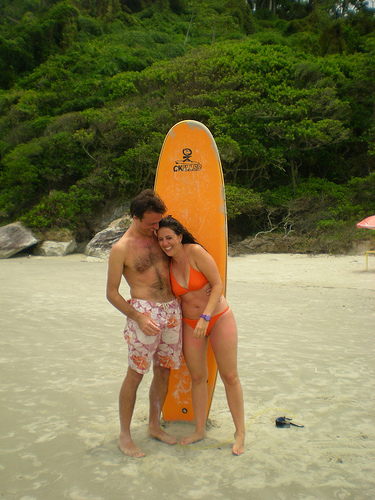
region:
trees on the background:
[30, 124, 124, 225]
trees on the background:
[243, 144, 328, 261]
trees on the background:
[333, 133, 374, 242]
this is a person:
[155, 221, 262, 454]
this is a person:
[86, 189, 180, 469]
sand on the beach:
[30, 351, 96, 436]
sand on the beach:
[65, 377, 118, 443]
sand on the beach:
[260, 441, 310, 480]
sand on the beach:
[253, 304, 324, 365]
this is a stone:
[28, 221, 79, 256]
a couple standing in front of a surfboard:
[65, 116, 246, 472]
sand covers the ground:
[0, 245, 371, 497]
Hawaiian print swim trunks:
[109, 292, 193, 383]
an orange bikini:
[161, 260, 239, 346]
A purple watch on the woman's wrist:
[195, 303, 216, 335]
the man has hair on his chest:
[122, 239, 173, 308]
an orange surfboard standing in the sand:
[137, 103, 237, 431]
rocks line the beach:
[0, 208, 137, 271]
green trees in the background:
[4, 0, 374, 250]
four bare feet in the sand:
[106, 410, 258, 467]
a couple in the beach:
[96, 183, 258, 462]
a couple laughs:
[100, 187, 260, 464]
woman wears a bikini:
[151, 217, 259, 459]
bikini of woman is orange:
[153, 217, 254, 463]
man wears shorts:
[87, 183, 174, 463]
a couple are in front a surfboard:
[101, 113, 257, 466]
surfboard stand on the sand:
[144, 110, 232, 452]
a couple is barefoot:
[94, 180, 264, 472]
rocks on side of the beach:
[6, 191, 133, 262]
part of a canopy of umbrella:
[350, 206, 373, 239]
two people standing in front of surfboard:
[110, 109, 248, 457]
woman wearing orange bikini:
[159, 220, 253, 457]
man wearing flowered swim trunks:
[100, 189, 187, 462]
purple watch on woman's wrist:
[197, 315, 210, 322]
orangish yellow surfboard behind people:
[148, 114, 229, 425]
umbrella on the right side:
[360, 206, 373, 274]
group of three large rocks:
[2, 211, 130, 255]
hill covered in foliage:
[11, 7, 359, 234]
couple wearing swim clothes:
[105, 192, 252, 455]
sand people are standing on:
[7, 256, 363, 496]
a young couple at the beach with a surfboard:
[87, 115, 260, 462]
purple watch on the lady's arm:
[199, 310, 214, 323]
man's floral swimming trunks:
[106, 290, 187, 375]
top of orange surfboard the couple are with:
[149, 120, 244, 262]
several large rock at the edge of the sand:
[8, 214, 122, 256]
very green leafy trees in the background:
[215, 69, 353, 168]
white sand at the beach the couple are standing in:
[253, 284, 345, 377]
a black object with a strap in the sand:
[267, 411, 308, 431]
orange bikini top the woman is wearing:
[164, 261, 207, 299]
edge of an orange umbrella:
[352, 214, 374, 228]